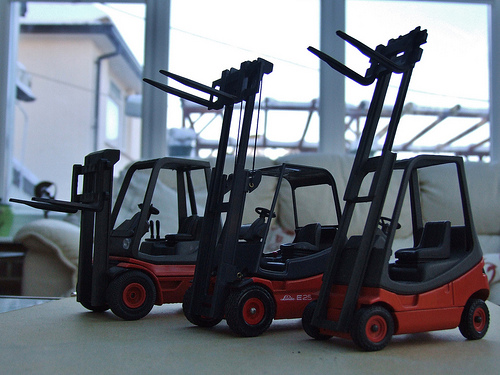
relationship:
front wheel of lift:
[110, 268, 159, 317] [66, 144, 233, 327]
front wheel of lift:
[153, 50, 358, 340] [163, 124, 359, 361]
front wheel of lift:
[353, 310, 393, 348] [302, 12, 487, 342]